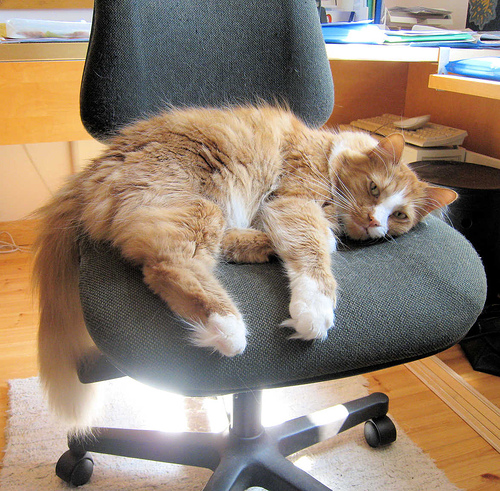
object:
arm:
[263, 173, 340, 350]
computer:
[402, 144, 471, 159]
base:
[53, 389, 395, 489]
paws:
[190, 289, 336, 353]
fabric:
[98, 19, 330, 134]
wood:
[407, 397, 459, 459]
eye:
[368, 179, 380, 198]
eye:
[389, 210, 408, 221]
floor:
[0, 236, 500, 489]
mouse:
[352, 105, 470, 148]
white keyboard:
[355, 107, 473, 149]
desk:
[319, 9, 498, 204]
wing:
[35, 105, 455, 430]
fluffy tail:
[31, 197, 94, 458]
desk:
[2, 18, 477, 152]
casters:
[363, 409, 408, 446]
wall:
[2, 62, 86, 147]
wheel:
[364, 416, 399, 446]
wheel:
[55, 449, 93, 485]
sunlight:
[59, 353, 366, 485]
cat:
[23, 98, 462, 358]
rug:
[6, 362, 450, 489]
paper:
[334, 11, 385, 59]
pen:
[345, 3, 363, 27]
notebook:
[364, 15, 483, 65]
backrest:
[85, 13, 365, 125]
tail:
[26, 168, 112, 459]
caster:
[59, 414, 221, 478]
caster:
[281, 392, 402, 457]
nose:
[354, 205, 390, 241]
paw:
[268, 260, 345, 345]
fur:
[286, 293, 322, 329]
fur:
[206, 321, 239, 349]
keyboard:
[350, 108, 468, 148]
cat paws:
[285, 272, 340, 344]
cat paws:
[182, 301, 249, 362]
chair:
[53, 0, 488, 490]